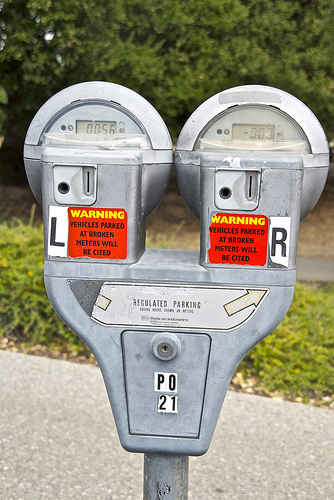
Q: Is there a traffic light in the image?
A: No, there are no traffic lights.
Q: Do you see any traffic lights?
A: No, there are no traffic lights.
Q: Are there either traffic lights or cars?
A: No, there are no traffic lights or cars.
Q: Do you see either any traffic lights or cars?
A: No, there are no traffic lights or cars.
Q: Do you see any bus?
A: No, there are no buses.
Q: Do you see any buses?
A: No, there are no buses.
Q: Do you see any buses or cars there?
A: No, there are no buses or cars.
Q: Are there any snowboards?
A: No, there are no snowboards.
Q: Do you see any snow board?
A: No, there are no snowboards.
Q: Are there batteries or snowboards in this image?
A: No, there are no snowboards or batteries.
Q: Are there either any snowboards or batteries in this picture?
A: No, there are no snowboards or batteries.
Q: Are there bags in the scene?
A: No, there are no bags.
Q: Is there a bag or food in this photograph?
A: No, there are no bags or food.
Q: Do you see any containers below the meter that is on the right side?
A: Yes, there is a container below the parking meter.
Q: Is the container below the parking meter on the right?
A: Yes, the container is below the parking meter.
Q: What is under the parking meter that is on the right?
A: The container is under the parking meter.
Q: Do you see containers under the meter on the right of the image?
A: Yes, there is a container under the meter.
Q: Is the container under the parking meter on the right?
A: Yes, the container is under the parking meter.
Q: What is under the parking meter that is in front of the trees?
A: The container is under the parking meter.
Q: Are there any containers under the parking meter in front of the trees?
A: Yes, there is a container under the parking meter.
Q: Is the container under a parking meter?
A: Yes, the container is under a parking meter.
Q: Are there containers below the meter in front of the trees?
A: Yes, there is a container below the meter.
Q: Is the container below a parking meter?
A: Yes, the container is below a parking meter.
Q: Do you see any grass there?
A: Yes, there is grass.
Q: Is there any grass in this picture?
A: Yes, there is grass.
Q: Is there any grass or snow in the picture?
A: Yes, there is grass.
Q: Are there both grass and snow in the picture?
A: No, there is grass but no snow.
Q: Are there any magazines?
A: No, there are no magazines.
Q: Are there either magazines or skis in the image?
A: No, there are no magazines or skis.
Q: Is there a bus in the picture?
A: No, there are no buses.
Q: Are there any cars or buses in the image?
A: No, there are no buses or cars.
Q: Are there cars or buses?
A: No, there are no cars or buses.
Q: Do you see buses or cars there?
A: No, there are no cars or buses.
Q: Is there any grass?
A: Yes, there is grass.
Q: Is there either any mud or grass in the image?
A: Yes, there is grass.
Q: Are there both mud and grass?
A: No, there is grass but no mud.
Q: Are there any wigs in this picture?
A: No, there are no wigs.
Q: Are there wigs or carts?
A: No, there are no wigs or carts.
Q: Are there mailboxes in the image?
A: No, there are no mailboxes.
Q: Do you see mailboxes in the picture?
A: No, there are no mailboxes.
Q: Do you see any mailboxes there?
A: No, there are no mailboxes.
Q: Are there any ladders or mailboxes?
A: No, there are no mailboxes or ladders.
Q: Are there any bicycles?
A: No, there are no bicycles.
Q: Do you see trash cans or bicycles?
A: No, there are no bicycles or trash cans.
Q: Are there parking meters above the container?
A: Yes, there is a parking meter above the container.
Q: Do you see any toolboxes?
A: No, there are no toolboxes.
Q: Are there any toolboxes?
A: No, there are no toolboxes.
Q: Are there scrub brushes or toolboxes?
A: No, there are no toolboxes or scrub brushes.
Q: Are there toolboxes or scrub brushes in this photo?
A: No, there are no toolboxes or scrub brushes.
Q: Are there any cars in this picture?
A: No, there are no cars.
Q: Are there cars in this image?
A: No, there are no cars.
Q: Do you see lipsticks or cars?
A: No, there are no cars or lipsticks.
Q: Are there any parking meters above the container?
A: Yes, there is a parking meter above the container.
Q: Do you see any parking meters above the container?
A: Yes, there is a parking meter above the container.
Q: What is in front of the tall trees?
A: The parking meter is in front of the trees.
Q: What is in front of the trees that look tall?
A: The parking meter is in front of the trees.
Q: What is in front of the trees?
A: The parking meter is in front of the trees.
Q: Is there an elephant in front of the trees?
A: No, there is a parking meter in front of the trees.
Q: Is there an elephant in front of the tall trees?
A: No, there is a parking meter in front of the trees.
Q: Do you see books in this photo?
A: No, there are no books.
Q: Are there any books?
A: No, there are no books.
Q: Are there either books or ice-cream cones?
A: No, there are no books or ice-cream cones.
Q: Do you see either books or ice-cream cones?
A: No, there are no books or ice-cream cones.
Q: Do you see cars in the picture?
A: No, there are no cars.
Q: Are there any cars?
A: No, there are no cars.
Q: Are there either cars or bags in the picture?
A: No, there are no cars or bags.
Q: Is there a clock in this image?
A: No, there are no clocks.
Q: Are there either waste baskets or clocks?
A: No, there are no clocks or waste baskets.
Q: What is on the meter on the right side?
A: The sticker is on the parking meter.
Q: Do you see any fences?
A: No, there are no fences.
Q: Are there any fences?
A: No, there are no fences.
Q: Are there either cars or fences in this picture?
A: No, there are no fences or cars.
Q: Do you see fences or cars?
A: No, there are no fences or cars.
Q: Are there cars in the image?
A: No, there are no cars.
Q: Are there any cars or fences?
A: No, there are no cars or fences.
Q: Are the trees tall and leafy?
A: Yes, the trees are tall and leafy.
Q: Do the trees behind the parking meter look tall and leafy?
A: Yes, the trees are tall and leafy.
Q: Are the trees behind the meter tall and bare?
A: No, the trees are tall but leafy.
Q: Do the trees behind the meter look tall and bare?
A: No, the trees are tall but leafy.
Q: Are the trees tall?
A: Yes, the trees are tall.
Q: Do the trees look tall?
A: Yes, the trees are tall.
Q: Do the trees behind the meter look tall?
A: Yes, the trees are tall.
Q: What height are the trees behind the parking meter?
A: The trees are tall.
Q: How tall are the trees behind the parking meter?
A: The trees are tall.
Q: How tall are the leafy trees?
A: The trees are tall.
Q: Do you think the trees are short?
A: No, the trees are tall.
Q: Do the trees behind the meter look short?
A: No, the trees are tall.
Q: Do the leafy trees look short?
A: No, the trees are tall.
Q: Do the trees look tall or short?
A: The trees are tall.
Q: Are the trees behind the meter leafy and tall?
A: Yes, the trees are leafy and tall.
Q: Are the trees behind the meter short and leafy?
A: No, the trees are leafy but tall.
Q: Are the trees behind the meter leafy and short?
A: No, the trees are leafy but tall.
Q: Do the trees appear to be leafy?
A: Yes, the trees are leafy.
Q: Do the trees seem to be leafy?
A: Yes, the trees are leafy.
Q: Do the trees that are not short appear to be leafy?
A: Yes, the trees are leafy.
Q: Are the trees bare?
A: No, the trees are leafy.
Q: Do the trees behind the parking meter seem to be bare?
A: No, the trees are leafy.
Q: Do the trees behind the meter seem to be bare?
A: No, the trees are leafy.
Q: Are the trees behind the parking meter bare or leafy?
A: The trees are leafy.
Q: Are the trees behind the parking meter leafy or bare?
A: The trees are leafy.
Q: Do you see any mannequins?
A: No, there are no mannequins.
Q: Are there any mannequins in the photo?
A: No, there are no mannequins.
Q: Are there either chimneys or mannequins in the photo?
A: No, there are no mannequins or chimneys.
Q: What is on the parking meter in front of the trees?
A: The sticker is on the meter.